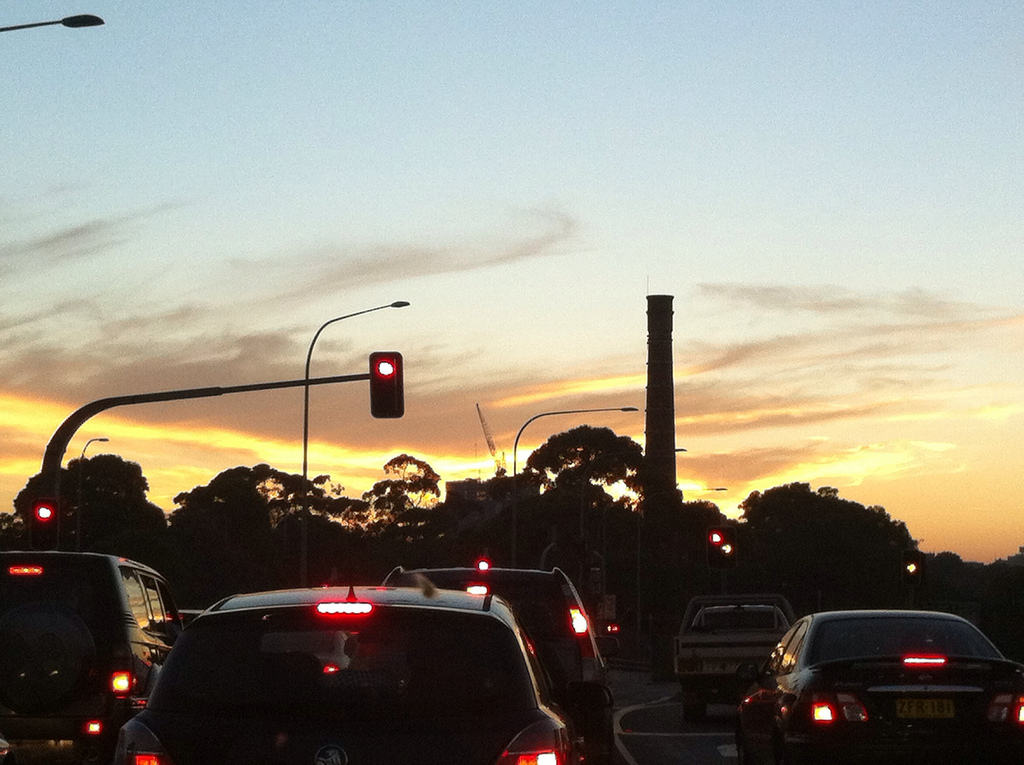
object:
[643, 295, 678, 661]
tower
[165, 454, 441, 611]
trees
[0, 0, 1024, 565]
sky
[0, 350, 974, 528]
yellow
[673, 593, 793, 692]
truck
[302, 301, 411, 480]
light pole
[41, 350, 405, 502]
pole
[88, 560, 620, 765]
lights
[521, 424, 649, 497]
tree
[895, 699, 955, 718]
plate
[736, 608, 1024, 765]
car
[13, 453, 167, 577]
trees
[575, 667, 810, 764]
road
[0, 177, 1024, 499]
clouds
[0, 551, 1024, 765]
cars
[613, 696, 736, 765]
lines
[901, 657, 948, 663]
light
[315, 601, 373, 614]
light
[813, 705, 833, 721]
light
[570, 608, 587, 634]
light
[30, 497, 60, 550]
light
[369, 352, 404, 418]
light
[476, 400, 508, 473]
crane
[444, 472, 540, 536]
building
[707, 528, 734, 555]
arrow